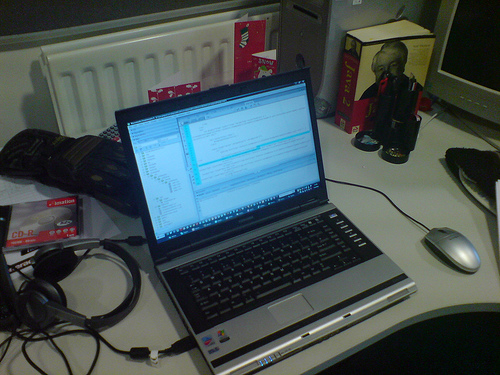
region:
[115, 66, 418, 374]
An older laptop computer.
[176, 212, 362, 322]
A laptop computer keyboard.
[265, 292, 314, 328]
A laptop computer touchpad.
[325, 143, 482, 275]
A computer mouse.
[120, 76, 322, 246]
A laptop computer monitor.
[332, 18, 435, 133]
A book.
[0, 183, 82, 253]
A CR-R case.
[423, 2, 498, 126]
An old CRT computer monitor.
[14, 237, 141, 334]
A pair of earphones sans the cable.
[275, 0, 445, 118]
An older macintosh desktop.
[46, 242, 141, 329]
this is a headphone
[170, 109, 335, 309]
this is a laptop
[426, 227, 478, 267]
this is a mouse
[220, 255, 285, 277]
these are the buttons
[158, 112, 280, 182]
this is the screen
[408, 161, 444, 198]
this is a table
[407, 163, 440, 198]
the table is white in color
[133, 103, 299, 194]
the laptop is on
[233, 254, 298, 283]
the buttons are black in color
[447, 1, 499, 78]
this is a television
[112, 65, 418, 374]
an open laptop computer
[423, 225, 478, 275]
a silver computer mouse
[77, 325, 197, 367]
a usb cable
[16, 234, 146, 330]
a pair of headphones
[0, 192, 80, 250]
a recordable CD case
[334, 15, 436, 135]
a paperback book on the desk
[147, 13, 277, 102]
several Christmas cards on the desk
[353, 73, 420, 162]
a black pencil holder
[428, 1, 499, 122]
a turned-off computer monitor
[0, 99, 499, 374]
a white desk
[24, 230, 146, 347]
stereo headphones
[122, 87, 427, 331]
a laptop with a document open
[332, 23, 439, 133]
a book titled Java 2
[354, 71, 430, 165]
a desk organizer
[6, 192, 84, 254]
recordable CDs with a gray and red label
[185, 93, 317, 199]
a document in Microsoft Word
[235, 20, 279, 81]
Christmas cards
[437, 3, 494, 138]
an old CRT computer monitor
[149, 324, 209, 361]
a USB connector for some headphones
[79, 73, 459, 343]
the laptop is on the desk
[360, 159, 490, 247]
the desk is white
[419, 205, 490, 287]
the mouse is silver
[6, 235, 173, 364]
the headphone is black and gray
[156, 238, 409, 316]
the keyboard is black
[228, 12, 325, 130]
the cards are red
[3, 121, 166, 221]
the glove is black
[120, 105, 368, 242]
the monitor is on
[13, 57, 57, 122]
the wall is white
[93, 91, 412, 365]
the laptop is on